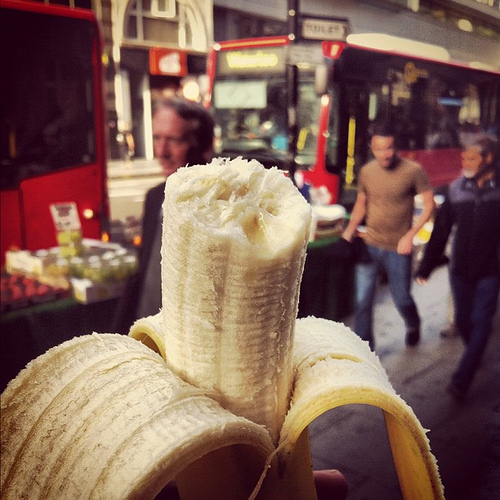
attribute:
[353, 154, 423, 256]
shirt — brown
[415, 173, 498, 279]
shirt — dark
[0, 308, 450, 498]
banana peel — yellow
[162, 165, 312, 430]
banana — half eaten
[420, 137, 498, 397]
people — in distance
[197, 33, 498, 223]
bus — red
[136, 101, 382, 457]
banana — partially eaten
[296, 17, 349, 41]
sign — black, white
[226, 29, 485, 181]
bus — large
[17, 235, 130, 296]
produce — canned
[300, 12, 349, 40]
street sign — on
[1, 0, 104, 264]
bus — red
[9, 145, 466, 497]
banana — partially eaten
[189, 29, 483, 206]
bus — red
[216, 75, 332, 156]
window — large